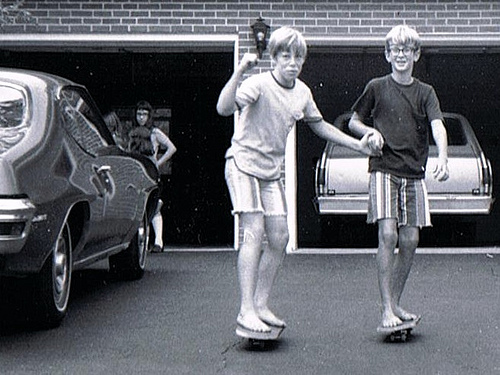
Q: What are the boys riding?
A: Skateboards.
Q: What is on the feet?
A: The boys are barefoot.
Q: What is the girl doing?
A: Watching the boys.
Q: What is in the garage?
A: A car.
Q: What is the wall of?
A: Brick.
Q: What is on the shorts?
A: Stripes.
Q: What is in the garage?
A: A car.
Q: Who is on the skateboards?
A: Two boys.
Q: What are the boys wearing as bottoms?
A: Striped shorts.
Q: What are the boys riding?
A: Skateboards.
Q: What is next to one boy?
A: A car.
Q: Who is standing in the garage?
A: A girl.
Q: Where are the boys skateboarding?
A: In the driveway.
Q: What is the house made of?
A: Brick.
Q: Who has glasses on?
A: The boy with the dark shirt on.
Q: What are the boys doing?
A: Riding skateboards.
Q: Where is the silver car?
A: Behind the boys.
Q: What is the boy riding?
A: A skateboard.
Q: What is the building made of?
A: Brick.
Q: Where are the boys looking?
A: Into the camera.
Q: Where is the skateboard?
A: On the ground.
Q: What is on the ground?
A: Two skateboards.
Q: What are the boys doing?
A: Holding hands and skating.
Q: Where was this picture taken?
A: In a driveway.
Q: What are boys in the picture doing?
A: Skateboarding.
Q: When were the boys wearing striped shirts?
A: While they were skateboarding.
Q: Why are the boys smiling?
A: Because they're skateboarding.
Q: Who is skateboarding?
A: Two boys.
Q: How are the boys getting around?
A: By skateboarding.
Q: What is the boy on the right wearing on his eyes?
A: Glasses.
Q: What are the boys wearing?
A: Striped shorts.